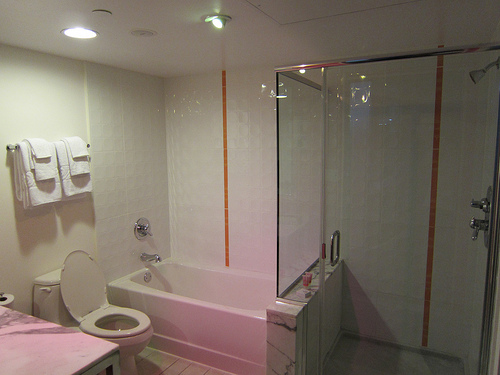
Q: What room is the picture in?
A: It is at the bathroom.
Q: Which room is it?
A: It is a bathroom.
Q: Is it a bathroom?
A: Yes, it is a bathroom.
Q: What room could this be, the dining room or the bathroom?
A: It is the bathroom.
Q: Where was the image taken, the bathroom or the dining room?
A: It was taken at the bathroom.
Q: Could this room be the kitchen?
A: No, it is the bathroom.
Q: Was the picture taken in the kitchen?
A: No, the picture was taken in the bathroom.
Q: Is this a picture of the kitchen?
A: No, the picture is showing the bathroom.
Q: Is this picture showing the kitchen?
A: No, the picture is showing the bathroom.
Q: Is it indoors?
A: Yes, it is indoors.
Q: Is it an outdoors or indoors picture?
A: It is indoors.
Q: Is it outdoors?
A: No, it is indoors.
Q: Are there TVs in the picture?
A: No, there are no tvs.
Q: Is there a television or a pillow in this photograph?
A: No, there are no televisions or pillows.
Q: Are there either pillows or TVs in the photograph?
A: No, there are no TVs or pillows.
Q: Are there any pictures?
A: No, there are no pictures.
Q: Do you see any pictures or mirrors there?
A: No, there are no pictures or mirrors.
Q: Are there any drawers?
A: No, there are no drawers.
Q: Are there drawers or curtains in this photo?
A: No, there are no drawers or curtains.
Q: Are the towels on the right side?
A: No, the towels are on the left of the image.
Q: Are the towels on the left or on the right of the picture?
A: The towels are on the left of the image.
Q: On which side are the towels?
A: The towels are on the left of the image.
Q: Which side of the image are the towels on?
A: The towels are on the left of the image.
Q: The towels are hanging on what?
A: The towels are hanging on the wall.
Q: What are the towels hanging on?
A: The towels are hanging on the wall.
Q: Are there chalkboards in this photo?
A: No, there are no chalkboards.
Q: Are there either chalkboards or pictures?
A: No, there are no chalkboards or pictures.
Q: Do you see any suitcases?
A: No, there are no suitcases.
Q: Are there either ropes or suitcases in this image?
A: No, there are no suitcases or ropes.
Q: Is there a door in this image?
A: Yes, there is a door.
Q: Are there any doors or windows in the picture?
A: Yes, there is a door.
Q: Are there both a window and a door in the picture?
A: No, there is a door but no windows.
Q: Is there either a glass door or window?
A: Yes, there is a glass door.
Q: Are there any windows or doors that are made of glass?
A: Yes, the door is made of glass.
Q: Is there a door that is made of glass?
A: Yes, there is a door that is made of glass.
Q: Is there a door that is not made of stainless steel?
A: Yes, there is a door that is made of glass.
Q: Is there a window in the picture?
A: No, there are no windows.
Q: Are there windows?
A: No, there are no windows.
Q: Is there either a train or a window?
A: No, there are no windows or trains.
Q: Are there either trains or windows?
A: No, there are no windows or trains.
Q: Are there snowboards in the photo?
A: No, there are no snowboards.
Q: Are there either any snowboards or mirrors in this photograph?
A: No, there are no snowboards or mirrors.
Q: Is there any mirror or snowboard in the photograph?
A: No, there are no snowboards or mirrors.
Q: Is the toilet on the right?
A: No, the toilet is on the left of the image.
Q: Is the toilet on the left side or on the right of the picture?
A: The toilet is on the left of the image.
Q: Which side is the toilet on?
A: The toilet is on the left of the image.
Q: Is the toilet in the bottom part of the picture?
A: Yes, the toilet is in the bottom of the image.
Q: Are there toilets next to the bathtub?
A: Yes, there is a toilet next to the bathtub.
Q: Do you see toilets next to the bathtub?
A: Yes, there is a toilet next to the bathtub.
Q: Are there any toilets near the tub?
A: Yes, there is a toilet near the tub.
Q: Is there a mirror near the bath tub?
A: No, there is a toilet near the bath tub.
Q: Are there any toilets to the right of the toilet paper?
A: Yes, there is a toilet to the right of the toilet paper.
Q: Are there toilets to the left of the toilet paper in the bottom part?
A: No, the toilet is to the right of the toilet paper.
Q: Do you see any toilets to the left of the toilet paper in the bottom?
A: No, the toilet is to the right of the toilet paper.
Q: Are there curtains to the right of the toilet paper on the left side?
A: No, there is a toilet to the right of the toilet paper.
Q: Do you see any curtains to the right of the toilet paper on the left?
A: No, there is a toilet to the right of the toilet paper.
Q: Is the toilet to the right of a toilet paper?
A: Yes, the toilet is to the right of a toilet paper.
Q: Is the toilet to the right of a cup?
A: No, the toilet is to the right of a toilet paper.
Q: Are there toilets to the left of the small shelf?
A: Yes, there is a toilet to the left of the shelf.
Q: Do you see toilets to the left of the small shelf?
A: Yes, there is a toilet to the left of the shelf.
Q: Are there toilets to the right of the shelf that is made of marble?
A: No, the toilet is to the left of the shelf.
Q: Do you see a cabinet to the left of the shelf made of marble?
A: No, there is a toilet to the left of the shelf.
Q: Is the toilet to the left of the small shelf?
A: Yes, the toilet is to the left of the shelf.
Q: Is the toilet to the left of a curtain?
A: No, the toilet is to the left of the shelf.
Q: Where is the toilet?
A: The toilet is in the bathroom.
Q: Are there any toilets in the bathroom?
A: Yes, there is a toilet in the bathroom.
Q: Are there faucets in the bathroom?
A: No, there is a toilet in the bathroom.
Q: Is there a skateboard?
A: No, there are no skateboards.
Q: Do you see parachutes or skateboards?
A: No, there are no skateboards or parachutes.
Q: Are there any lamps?
A: No, there are no lamps.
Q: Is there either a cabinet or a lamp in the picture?
A: No, there are no lamps or cabinets.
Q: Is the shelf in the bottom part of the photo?
A: Yes, the shelf is in the bottom of the image.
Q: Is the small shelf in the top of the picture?
A: No, the shelf is in the bottom of the image.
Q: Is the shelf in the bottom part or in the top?
A: The shelf is in the bottom of the image.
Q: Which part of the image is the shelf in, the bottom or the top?
A: The shelf is in the bottom of the image.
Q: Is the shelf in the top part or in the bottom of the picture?
A: The shelf is in the bottom of the image.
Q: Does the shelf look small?
A: Yes, the shelf is small.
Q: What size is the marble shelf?
A: The shelf is small.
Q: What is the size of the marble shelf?
A: The shelf is small.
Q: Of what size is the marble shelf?
A: The shelf is small.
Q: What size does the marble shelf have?
A: The shelf has small size.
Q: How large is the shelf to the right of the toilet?
A: The shelf is small.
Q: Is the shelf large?
A: No, the shelf is small.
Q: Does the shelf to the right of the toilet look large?
A: No, the shelf is small.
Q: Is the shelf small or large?
A: The shelf is small.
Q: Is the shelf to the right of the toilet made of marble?
A: Yes, the shelf is made of marble.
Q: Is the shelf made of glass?
A: No, the shelf is made of marble.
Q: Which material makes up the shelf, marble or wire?
A: The shelf is made of marble.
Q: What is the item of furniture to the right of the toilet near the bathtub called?
A: The piece of furniture is a shelf.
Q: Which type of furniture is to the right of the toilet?
A: The piece of furniture is a shelf.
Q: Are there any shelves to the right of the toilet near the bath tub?
A: Yes, there is a shelf to the right of the toilet.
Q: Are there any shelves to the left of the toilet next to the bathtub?
A: No, the shelf is to the right of the toilet.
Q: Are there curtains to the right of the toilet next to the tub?
A: No, there is a shelf to the right of the toilet.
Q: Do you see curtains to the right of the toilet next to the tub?
A: No, there is a shelf to the right of the toilet.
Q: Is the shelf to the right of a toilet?
A: Yes, the shelf is to the right of a toilet.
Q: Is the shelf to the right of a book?
A: No, the shelf is to the right of a toilet.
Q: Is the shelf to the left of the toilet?
A: No, the shelf is to the right of the toilet.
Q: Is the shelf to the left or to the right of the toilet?
A: The shelf is to the right of the toilet.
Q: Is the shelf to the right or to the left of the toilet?
A: The shelf is to the right of the toilet.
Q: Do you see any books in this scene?
A: No, there are no books.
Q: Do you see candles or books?
A: No, there are no books or candles.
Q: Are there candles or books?
A: No, there are no books or candles.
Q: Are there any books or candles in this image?
A: No, there are no books or candles.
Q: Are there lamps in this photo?
A: No, there are no lamps.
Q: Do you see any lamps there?
A: No, there are no lamps.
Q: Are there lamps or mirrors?
A: No, there are no lamps or mirrors.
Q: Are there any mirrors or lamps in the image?
A: No, there are no lamps or mirrors.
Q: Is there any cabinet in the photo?
A: No, there are no cabinets.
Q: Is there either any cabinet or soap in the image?
A: No, there are no cabinets or soaps.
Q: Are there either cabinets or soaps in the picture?
A: No, there are no cabinets or soaps.